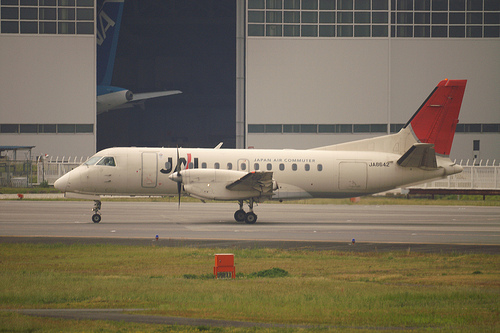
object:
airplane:
[53, 79, 468, 223]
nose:
[54, 178, 64, 184]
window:
[291, 163, 297, 171]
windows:
[97, 157, 116, 167]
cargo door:
[338, 162, 367, 190]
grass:
[0, 251, 118, 316]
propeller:
[176, 145, 182, 210]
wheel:
[244, 212, 258, 224]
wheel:
[234, 210, 246, 222]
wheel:
[92, 214, 102, 223]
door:
[141, 153, 157, 188]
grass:
[287, 251, 462, 310]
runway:
[0, 199, 500, 243]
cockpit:
[82, 154, 118, 167]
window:
[241, 163, 246, 170]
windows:
[213, 162, 219, 169]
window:
[267, 163, 273, 171]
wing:
[226, 171, 274, 192]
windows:
[317, 164, 323, 171]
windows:
[304, 164, 310, 171]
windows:
[202, 162, 207, 169]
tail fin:
[399, 79, 467, 157]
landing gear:
[233, 196, 270, 224]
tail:
[396, 79, 468, 188]